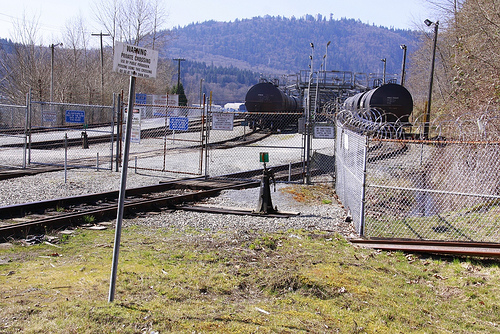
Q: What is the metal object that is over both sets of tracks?
A: A fence.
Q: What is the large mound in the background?
A: A hill.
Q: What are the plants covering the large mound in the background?
A: Trees.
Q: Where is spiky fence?
A: Near a railroad.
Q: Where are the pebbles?
A: Next the rail?.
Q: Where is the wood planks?
A: On the rail.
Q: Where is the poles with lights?
A: On side the road.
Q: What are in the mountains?
A: Trees.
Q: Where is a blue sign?
A: On a metal door.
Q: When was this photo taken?
A: Daytime.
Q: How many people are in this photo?
A: Zero.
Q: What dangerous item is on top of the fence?
A: Barbed Wire.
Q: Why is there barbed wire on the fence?
A: Keep people out.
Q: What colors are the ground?
A: Brown, green.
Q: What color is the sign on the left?
A: White.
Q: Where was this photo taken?
A: By the trains.